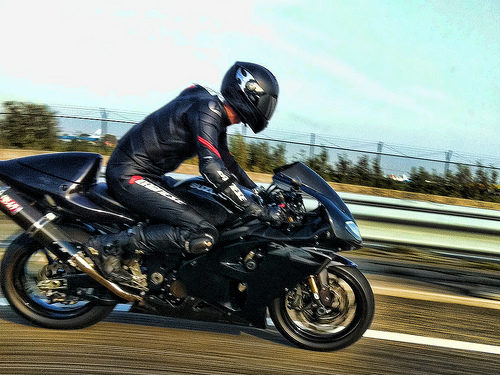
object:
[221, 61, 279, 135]
helmet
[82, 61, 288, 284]
person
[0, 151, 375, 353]
motorcycle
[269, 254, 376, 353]
front tire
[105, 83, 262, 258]
black suit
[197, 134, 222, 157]
red stripe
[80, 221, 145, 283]
right boot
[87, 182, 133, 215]
black seat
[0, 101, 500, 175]
bridge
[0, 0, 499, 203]
background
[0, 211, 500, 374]
road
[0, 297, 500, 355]
white stripe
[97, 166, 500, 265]
guard rail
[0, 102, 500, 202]
plants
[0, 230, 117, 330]
rear tire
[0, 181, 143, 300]
tailpipe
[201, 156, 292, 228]
right glove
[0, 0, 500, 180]
sky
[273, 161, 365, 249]
windshield